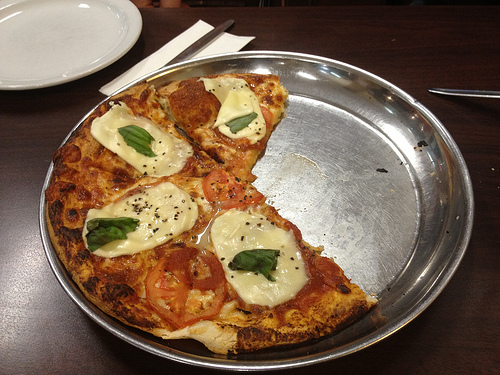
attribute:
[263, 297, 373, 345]
crust — brown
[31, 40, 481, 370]
dish — silver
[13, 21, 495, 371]
table — dark, brown, wooden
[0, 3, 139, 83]
plate — white, empty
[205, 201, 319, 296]
mozzarella — sliced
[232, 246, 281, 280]
herb — green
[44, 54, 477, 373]
pan — silver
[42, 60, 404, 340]
pizza — cooked, partially eaten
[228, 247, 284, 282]
basil leaf — green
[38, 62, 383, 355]
pizza — partially eaten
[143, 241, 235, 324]
tomato — red, sliced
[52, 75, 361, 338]
pizza — partially eaten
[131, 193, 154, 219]
seasoning — green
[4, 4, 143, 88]
plate — white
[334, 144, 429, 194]
pan — silver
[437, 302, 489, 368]
table — wooden